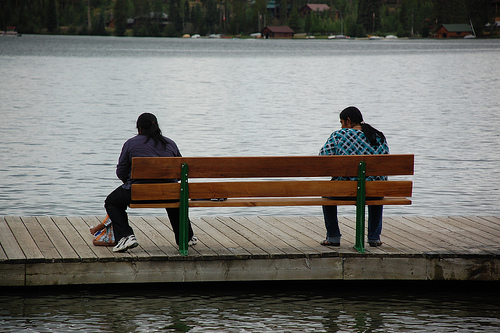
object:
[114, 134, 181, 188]
shirt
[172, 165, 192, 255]
green pole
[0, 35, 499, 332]
water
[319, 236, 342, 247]
sandals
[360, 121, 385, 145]
pony tail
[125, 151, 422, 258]
toy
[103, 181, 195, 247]
black pants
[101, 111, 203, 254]
person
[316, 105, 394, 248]
person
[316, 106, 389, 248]
woman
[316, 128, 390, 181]
checkered shirt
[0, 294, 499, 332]
ripples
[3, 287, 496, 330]
reflections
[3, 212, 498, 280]
pier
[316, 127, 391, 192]
striped shirt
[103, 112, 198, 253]
woman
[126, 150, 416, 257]
bench